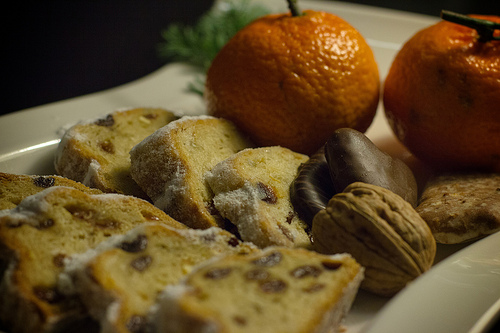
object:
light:
[296, 23, 359, 78]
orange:
[201, 0, 381, 156]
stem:
[286, 0, 306, 17]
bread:
[0, 107, 366, 333]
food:
[0, 0, 500, 333]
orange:
[381, 9, 500, 173]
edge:
[470, 299, 500, 333]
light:
[0, 136, 68, 171]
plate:
[0, 0, 500, 333]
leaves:
[158, 0, 270, 99]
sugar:
[171, 115, 221, 129]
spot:
[115, 233, 153, 271]